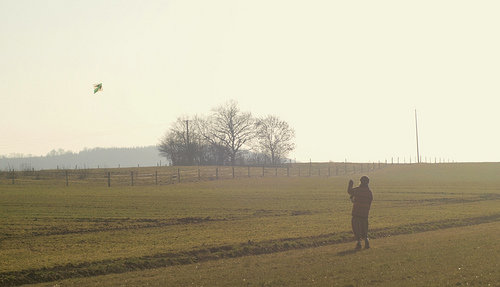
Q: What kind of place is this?
A: It is a field.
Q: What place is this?
A: It is a field.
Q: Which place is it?
A: It is a field.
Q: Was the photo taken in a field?
A: Yes, it was taken in a field.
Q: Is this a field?
A: Yes, it is a field.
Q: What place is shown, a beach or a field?
A: It is a field.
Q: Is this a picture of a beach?
A: No, the picture is showing a field.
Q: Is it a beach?
A: No, it is a field.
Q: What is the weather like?
A: It is clear.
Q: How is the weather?
A: It is clear.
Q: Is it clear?
A: Yes, it is clear.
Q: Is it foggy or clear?
A: It is clear.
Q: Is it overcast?
A: No, it is clear.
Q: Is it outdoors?
A: Yes, it is outdoors.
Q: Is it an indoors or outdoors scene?
A: It is outdoors.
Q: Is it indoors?
A: No, it is outdoors.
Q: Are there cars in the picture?
A: No, there are no cars.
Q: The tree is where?
A: The tree is in the field.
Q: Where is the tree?
A: The tree is in the field.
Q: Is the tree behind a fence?
A: Yes, the tree is behind a fence.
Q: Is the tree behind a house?
A: No, the tree is behind a fence.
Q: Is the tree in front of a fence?
A: No, the tree is behind a fence.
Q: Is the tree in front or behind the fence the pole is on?
A: The tree is behind the fence.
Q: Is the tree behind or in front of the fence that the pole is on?
A: The tree is behind the fence.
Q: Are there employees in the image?
A: No, there are no employees.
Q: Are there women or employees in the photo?
A: No, there are no employees or women.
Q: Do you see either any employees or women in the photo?
A: No, there are no employees or women.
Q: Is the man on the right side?
A: Yes, the man is on the right of the image.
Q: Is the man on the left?
A: No, the man is on the right of the image.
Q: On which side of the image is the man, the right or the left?
A: The man is on the right of the image.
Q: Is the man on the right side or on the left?
A: The man is on the right of the image.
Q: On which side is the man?
A: The man is on the right of the image.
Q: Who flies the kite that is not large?
A: The man flies the kite.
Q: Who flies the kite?
A: The man flies the kite.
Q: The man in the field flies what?
A: The man flies the kite.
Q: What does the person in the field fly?
A: The man flies the kite.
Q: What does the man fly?
A: The man flies the kite.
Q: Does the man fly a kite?
A: Yes, the man flies a kite.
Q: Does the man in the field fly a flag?
A: No, the man flies a kite.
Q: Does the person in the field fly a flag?
A: No, the man flies a kite.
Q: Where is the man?
A: The man is in the field.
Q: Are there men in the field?
A: Yes, there is a man in the field.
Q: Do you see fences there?
A: Yes, there is a fence.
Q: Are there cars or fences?
A: Yes, there is a fence.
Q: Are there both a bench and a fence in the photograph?
A: No, there is a fence but no benches.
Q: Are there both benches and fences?
A: No, there is a fence but no benches.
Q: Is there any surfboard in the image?
A: No, there are no surfboards.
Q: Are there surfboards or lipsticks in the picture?
A: No, there are no surfboards or lipsticks.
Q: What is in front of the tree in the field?
A: The fence is in front of the tree.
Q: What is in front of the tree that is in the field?
A: The fence is in front of the tree.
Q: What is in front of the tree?
A: The fence is in front of the tree.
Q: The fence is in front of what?
A: The fence is in front of the tree.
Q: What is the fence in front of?
A: The fence is in front of the tree.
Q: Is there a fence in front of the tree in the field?
A: Yes, there is a fence in front of the tree.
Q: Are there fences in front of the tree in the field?
A: Yes, there is a fence in front of the tree.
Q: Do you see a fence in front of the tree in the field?
A: Yes, there is a fence in front of the tree.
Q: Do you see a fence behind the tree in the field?
A: No, the fence is in front of the tree.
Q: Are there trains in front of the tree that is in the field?
A: No, there is a fence in front of the tree.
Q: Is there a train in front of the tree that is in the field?
A: No, there is a fence in front of the tree.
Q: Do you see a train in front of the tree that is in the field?
A: No, there is a fence in front of the tree.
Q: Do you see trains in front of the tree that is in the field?
A: No, there is a fence in front of the tree.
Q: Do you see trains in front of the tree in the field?
A: No, there is a fence in front of the tree.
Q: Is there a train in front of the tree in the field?
A: No, there is a fence in front of the tree.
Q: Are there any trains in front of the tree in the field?
A: No, there is a fence in front of the tree.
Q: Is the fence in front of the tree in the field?
A: Yes, the fence is in front of the tree.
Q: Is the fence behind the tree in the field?
A: No, the fence is in front of the tree.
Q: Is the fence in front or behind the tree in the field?
A: The fence is in front of the tree.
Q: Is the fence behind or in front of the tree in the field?
A: The fence is in front of the tree.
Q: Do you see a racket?
A: No, there are no rackets.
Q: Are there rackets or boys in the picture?
A: No, there are no rackets or boys.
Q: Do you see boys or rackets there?
A: No, there are no rackets or boys.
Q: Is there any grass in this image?
A: Yes, there is grass.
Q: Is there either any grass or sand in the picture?
A: Yes, there is grass.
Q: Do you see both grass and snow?
A: No, there is grass but no snow.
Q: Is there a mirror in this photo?
A: No, there are no mirrors.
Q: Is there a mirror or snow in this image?
A: No, there are no mirrors or snow.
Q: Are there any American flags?
A: No, there are no American flags.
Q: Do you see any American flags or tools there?
A: No, there are no American flags or tools.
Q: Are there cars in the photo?
A: No, there are no cars.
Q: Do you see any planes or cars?
A: No, there are no cars or planes.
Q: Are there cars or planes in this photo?
A: No, there are no cars or planes.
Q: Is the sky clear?
A: Yes, the sky is clear.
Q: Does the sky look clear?
A: Yes, the sky is clear.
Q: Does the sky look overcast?
A: No, the sky is clear.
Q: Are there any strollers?
A: No, there are no strollers.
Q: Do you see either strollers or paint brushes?
A: No, there are no strollers or paint brushes.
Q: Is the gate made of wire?
A: Yes, the gate is made of wire.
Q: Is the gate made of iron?
A: No, the gate is made of wire.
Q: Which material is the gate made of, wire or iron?
A: The gate is made of wire.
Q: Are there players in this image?
A: No, there are no players.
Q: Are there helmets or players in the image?
A: No, there are no players or helmets.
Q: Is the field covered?
A: Yes, the field is covered.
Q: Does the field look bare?
A: No, the field is covered.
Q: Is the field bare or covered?
A: The field is covered.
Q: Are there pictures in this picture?
A: No, there are no pictures.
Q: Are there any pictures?
A: No, there are no pictures.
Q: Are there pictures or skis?
A: No, there are no pictures or skis.